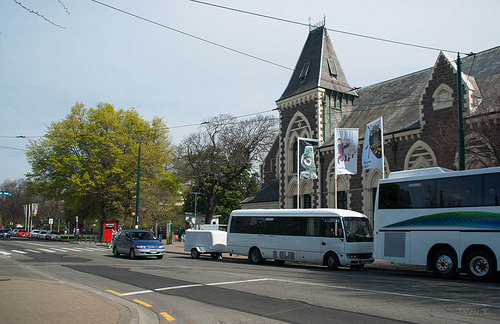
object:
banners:
[334, 128, 359, 175]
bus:
[226, 209, 374, 270]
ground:
[0, 236, 499, 322]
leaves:
[79, 135, 127, 180]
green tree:
[23, 101, 176, 242]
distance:
[5, 59, 278, 279]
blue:
[130, 240, 157, 246]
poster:
[297, 137, 319, 180]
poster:
[334, 128, 359, 174]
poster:
[361, 115, 384, 169]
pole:
[297, 136, 299, 210]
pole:
[334, 128, 338, 209]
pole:
[381, 116, 385, 179]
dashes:
[105, 289, 121, 296]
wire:
[0, 109, 277, 138]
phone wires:
[190, 0, 472, 56]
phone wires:
[85, 0, 294, 70]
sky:
[0, 0, 499, 188]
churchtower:
[274, 13, 359, 209]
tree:
[171, 113, 284, 224]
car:
[110, 229, 166, 259]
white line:
[120, 278, 335, 297]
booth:
[102, 221, 115, 242]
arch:
[404, 139, 438, 170]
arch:
[452, 132, 498, 171]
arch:
[361, 155, 391, 230]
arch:
[325, 157, 351, 210]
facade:
[237, 19, 500, 230]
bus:
[372, 166, 500, 280]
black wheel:
[461, 244, 496, 282]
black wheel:
[429, 244, 459, 280]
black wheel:
[323, 251, 339, 268]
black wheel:
[248, 246, 266, 264]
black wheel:
[349, 263, 363, 270]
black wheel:
[274, 259, 285, 264]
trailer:
[185, 229, 227, 259]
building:
[237, 13, 499, 230]